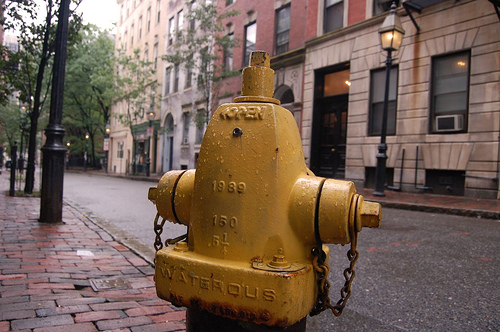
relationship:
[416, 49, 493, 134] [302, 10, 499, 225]
window of nearby building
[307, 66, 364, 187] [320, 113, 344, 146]
door with glass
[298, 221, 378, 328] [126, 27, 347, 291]
chain on a hydrant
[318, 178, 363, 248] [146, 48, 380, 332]
caps on fire hydrant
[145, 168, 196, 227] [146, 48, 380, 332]
caps on fire hydrant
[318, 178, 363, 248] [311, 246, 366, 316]
caps held on with chains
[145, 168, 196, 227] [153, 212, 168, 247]
caps held on with chains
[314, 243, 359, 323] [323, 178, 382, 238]
chain holding cap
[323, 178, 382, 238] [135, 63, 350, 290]
cap of fire hydrant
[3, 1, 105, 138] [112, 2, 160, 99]
trees near building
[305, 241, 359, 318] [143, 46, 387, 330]
chain on fire hydrant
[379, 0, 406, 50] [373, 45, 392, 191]
light on pole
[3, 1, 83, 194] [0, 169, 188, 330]
tree grow up out of sidewalk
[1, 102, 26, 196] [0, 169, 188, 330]
tree grow up out of sidewalk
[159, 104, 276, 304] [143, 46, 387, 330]
raised numbers on fire hydrant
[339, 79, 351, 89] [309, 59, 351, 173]
light over door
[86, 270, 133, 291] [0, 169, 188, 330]
cover in sidewalk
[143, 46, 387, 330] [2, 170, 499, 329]
fire hydrant on pavement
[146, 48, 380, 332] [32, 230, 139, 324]
fire hydrant next to sidewalk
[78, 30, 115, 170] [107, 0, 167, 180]
tree by building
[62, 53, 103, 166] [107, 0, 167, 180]
tree by building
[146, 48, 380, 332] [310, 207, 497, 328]
fire hydrant on street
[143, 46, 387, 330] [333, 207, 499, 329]
fire hydrant on street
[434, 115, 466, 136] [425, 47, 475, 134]
air conditioner in window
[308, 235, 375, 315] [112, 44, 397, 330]
chain on fire hydrant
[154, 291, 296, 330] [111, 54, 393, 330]
rust on hydrant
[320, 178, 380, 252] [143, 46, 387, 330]
cap on fire hydrant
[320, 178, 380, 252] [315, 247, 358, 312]
cap connected with chain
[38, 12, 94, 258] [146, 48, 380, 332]
pole near fire hydrant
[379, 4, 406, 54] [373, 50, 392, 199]
light on light pole